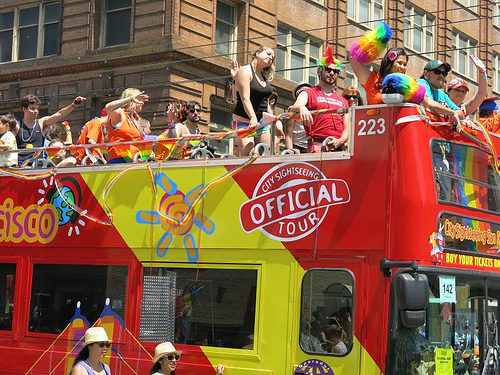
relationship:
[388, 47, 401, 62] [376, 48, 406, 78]
flower in hair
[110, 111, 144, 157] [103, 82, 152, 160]
tank top on woman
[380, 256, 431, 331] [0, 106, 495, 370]
mirror on bus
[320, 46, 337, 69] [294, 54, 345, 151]
mohawk on man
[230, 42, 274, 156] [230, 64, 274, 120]
woman on black top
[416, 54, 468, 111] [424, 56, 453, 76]
man wearing a hat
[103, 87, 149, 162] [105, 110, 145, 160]
woman wearing a orange t-shirt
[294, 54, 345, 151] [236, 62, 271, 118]
man wearing a tank top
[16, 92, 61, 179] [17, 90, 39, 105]
man with black hair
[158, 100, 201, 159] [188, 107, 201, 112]
man wearing sunglasses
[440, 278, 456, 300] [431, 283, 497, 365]
number posted on window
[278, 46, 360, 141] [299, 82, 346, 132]
man wearing a t shirt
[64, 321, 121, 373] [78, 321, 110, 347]
woman wearing a fedora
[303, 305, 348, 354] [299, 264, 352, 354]
reflection of crowd on window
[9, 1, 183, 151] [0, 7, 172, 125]
wall on side of building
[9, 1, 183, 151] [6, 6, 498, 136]
wall on side of building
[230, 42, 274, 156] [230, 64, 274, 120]
woman wearing black top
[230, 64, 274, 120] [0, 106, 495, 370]
black top standing on th bus